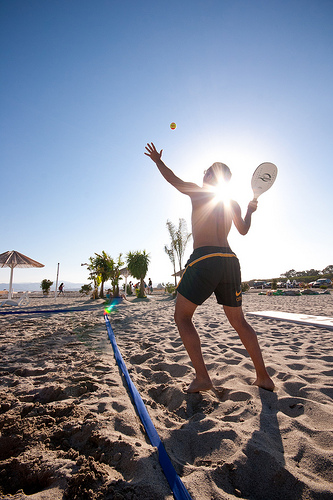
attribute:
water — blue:
[1, 284, 83, 290]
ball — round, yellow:
[167, 121, 176, 130]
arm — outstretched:
[141, 136, 200, 197]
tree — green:
[126, 248, 151, 296]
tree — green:
[109, 249, 122, 296]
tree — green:
[95, 247, 113, 295]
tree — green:
[83, 255, 100, 299]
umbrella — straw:
[2, 230, 58, 308]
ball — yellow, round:
[165, 116, 183, 139]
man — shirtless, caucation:
[142, 139, 277, 396]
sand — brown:
[1, 290, 332, 499]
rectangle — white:
[244, 305, 331, 336]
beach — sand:
[26, 292, 72, 355]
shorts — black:
[174, 245, 244, 307]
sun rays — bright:
[180, 160, 245, 227]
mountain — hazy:
[17, 283, 36, 293]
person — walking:
[58, 282, 66, 294]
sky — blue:
[0, 0, 332, 287]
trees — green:
[239, 263, 331, 288]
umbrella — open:
[6, 235, 45, 274]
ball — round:
[169, 121, 181, 128]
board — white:
[249, 301, 332, 340]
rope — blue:
[102, 295, 194, 499]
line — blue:
[103, 314, 192, 498]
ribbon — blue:
[103, 310, 189, 494]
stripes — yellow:
[185, 249, 238, 268]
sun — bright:
[186, 140, 251, 213]